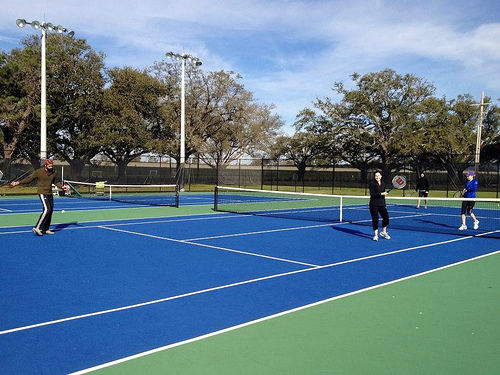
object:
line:
[160, 258, 310, 298]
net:
[190, 130, 496, 228]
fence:
[109, 151, 270, 191]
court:
[5, 15, 498, 371]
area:
[19, 233, 149, 283]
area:
[321, 315, 498, 353]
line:
[88, 218, 329, 272]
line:
[0, 226, 101, 237]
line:
[138, 215, 286, 227]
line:
[424, 209, 462, 221]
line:
[286, 205, 368, 215]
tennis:
[0, 155, 500, 372]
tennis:
[214, 183, 500, 237]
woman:
[363, 170, 392, 244]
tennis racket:
[387, 169, 411, 196]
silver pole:
[37, 30, 51, 161]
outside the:
[1, 30, 498, 203]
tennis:
[3, 150, 500, 200]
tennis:
[3, 234, 129, 305]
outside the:
[335, 302, 500, 374]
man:
[1, 158, 77, 239]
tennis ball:
[58, 208, 70, 215]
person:
[454, 170, 483, 236]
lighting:
[17, 13, 205, 168]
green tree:
[300, 67, 499, 194]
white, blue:
[3, 228, 360, 293]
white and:
[394, 175, 405, 190]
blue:
[462, 180, 480, 197]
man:
[414, 170, 433, 214]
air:
[60, 209, 68, 216]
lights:
[17, 15, 77, 44]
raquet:
[0, 172, 22, 189]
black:
[369, 184, 383, 226]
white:
[217, 194, 500, 223]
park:
[3, 2, 497, 372]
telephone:
[464, 91, 498, 174]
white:
[369, 227, 394, 244]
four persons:
[3, 157, 494, 243]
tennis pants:
[33, 195, 57, 227]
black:
[417, 190, 430, 198]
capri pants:
[462, 200, 478, 216]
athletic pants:
[369, 205, 390, 228]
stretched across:
[58, 176, 499, 238]